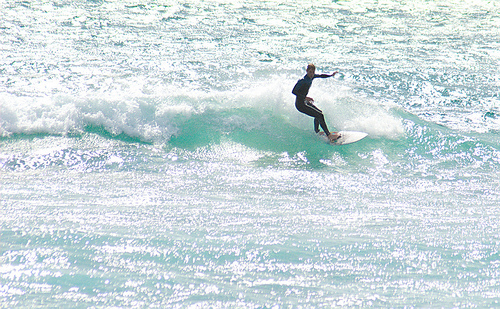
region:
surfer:
[278, 52, 333, 143]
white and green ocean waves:
[80, 41, 122, 78]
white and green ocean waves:
[317, 215, 357, 247]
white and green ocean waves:
[135, 165, 215, 226]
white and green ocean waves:
[190, 208, 242, 250]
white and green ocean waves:
[372, 41, 479, 79]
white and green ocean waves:
[131, 62, 189, 100]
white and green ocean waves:
[128, 131, 179, 172]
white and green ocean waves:
[81, 236, 142, 274]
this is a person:
[285, 59, 341, 145]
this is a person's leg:
[298, 97, 344, 142]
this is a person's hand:
[317, 67, 338, 79]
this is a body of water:
[187, 207, 383, 303]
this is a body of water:
[398, 116, 494, 300]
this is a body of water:
[13, 15, 100, 117]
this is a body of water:
[136, 20, 266, 140]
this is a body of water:
[347, 16, 468, 109]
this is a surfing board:
[318, 115, 369, 146]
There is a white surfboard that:
[361, 129, 368, 145]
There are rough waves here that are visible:
[123, 79, 150, 154]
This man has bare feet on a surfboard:
[329, 125, 335, 142]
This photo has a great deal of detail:
[111, 26, 277, 257]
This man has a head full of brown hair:
[306, 58, 311, 75]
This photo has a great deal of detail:
[128, 28, 321, 250]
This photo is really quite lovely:
[140, 17, 347, 268]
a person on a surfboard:
[285, 55, 340, 140]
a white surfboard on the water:
[315, 125, 365, 145]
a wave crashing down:
[0, 85, 200, 150]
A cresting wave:
[220, 75, 420, 160]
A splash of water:
[250, 70, 400, 135]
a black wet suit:
[290, 70, 330, 130]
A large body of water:
[0, 0, 490, 305]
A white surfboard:
[310, 125, 366, 145]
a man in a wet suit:
[288, 61, 346, 140]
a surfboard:
[304, 124, 371, 144]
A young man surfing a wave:
[278, 59, 379, 154]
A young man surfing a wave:
[279, 52, 381, 160]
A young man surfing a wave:
[275, 51, 380, 162]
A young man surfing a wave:
[273, 57, 375, 156]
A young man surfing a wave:
[279, 56, 375, 158]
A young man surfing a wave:
[273, 54, 376, 161]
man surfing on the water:
[290, 56, 368, 148]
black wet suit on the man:
[288, 60, 345, 140]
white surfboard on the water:
[307, 117, 369, 149]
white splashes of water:
[0, 80, 408, 152]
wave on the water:
[1, 61, 487, 157]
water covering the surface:
[0, 1, 496, 306]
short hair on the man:
[300, 58, 320, 78]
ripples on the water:
[1, 2, 498, 302]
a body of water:
[122, 50, 495, 295]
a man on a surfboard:
[261, 60, 439, 174]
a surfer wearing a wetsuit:
[270, 41, 386, 178]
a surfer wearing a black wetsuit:
[272, 21, 377, 156]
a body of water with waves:
[56, 46, 402, 284]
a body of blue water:
[125, 57, 390, 267]